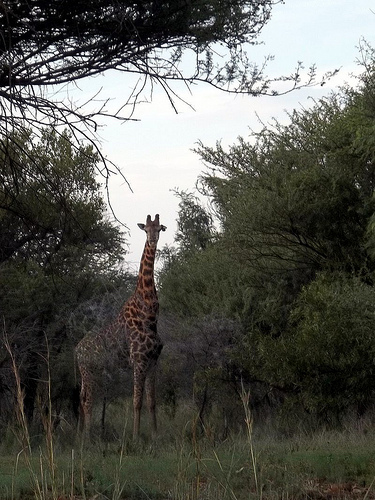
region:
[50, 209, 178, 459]
giraffe standing in field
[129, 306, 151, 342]
brown spots on giraffe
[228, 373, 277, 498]
tall plant blade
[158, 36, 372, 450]
tall leafy trees and foliage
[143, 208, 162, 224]
two ossicones on giraffe head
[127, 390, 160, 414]
two giraffe knees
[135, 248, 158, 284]
long giraffe neck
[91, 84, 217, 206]
white clouds in light blue sky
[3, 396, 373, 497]
field of tall green and yellowed grass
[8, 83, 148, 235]
brown, bare tree branches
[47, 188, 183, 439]
This is a picture of a giraffe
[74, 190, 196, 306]
The neck is very long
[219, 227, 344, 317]
These are old trees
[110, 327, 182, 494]
These are long legs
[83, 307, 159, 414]
There is only one giraffe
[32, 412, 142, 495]
There are no people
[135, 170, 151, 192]
The sun is not shining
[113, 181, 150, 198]
The sky is very cloudy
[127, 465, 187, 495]
These are weeds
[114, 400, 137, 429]
This is a leg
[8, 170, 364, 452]
A giraffe standing among trees.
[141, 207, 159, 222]
Ossicones on the giraffe's head.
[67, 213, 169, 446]
The giraffe has an orange spotted pattern.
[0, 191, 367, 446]
Trees on both sides of the giraffe.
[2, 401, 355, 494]
Wild grass on the ground.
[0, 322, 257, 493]
Tall strands of grass.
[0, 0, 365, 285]
White clouds in the sky.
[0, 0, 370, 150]
Blue sky behind the clouds.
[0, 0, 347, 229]
Tree limbs above the giraffe.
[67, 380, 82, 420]
Black hair on the end of the giraffe's tail.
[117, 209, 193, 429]
There is a large giraffe pictured in this photo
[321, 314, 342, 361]
There are dark green trees in the distance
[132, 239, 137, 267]
There is a patch of white sky that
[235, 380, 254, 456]
There is a stalk of yellow vegetation in the distance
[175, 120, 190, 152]
There is a patch of light blue sky also visible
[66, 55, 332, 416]
Jackson Mingus took this photo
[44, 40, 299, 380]
The season of this photo is summer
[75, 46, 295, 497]
This is taken in the country of South Africa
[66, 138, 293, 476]
This is taken in the continent of Africa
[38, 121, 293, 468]
This photo is of a lovely high quality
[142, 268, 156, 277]
Brown patch of fur on animal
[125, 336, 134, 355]
Brown patch of fur on animal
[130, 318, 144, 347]
Brown patch of fur on animal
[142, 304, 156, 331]
Brown patch of fur on animal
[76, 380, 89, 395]
Brown patch of fur on animal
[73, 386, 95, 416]
Brown patch of fur on animal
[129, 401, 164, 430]
Brown patch of fur on animal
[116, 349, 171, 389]
Brown patch of fur on animal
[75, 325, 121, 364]
Brown patch of fur on animal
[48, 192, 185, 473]
Large giraffe